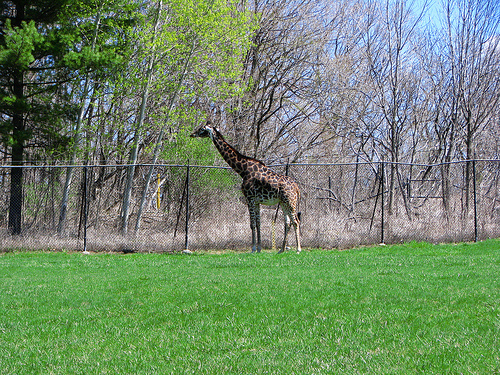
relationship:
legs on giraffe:
[283, 204, 300, 253] [188, 118, 303, 254]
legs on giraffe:
[281, 214, 291, 252] [188, 118, 303, 254]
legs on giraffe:
[254, 199, 262, 252] [188, 118, 303, 254]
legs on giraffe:
[247, 203, 256, 253] [188, 118, 303, 254]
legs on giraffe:
[242, 193, 308, 255] [188, 118, 303, 254]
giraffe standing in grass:
[188, 118, 303, 254] [2, 251, 499, 371]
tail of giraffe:
[295, 186, 302, 221] [188, 118, 303, 254]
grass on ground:
[2, 251, 499, 371] [1, 223, 497, 372]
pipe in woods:
[146, 171, 172, 218] [5, 2, 495, 254]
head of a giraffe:
[192, 119, 224, 144] [178, 105, 301, 243]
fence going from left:
[6, 156, 481, 250] [7, 10, 65, 280]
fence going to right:
[6, 156, 481, 250] [413, 23, 487, 307]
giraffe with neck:
[188, 118, 303, 254] [214, 136, 251, 176]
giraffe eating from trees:
[188, 118, 303, 254] [8, 7, 498, 158]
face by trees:
[187, 123, 204, 137] [69, 29, 370, 116]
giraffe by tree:
[188, 118, 303, 254] [24, 25, 489, 137]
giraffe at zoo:
[188, 118, 303, 254] [1, 4, 497, 372]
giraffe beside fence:
[188, 118, 303, 254] [6, 156, 481, 250]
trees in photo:
[363, 80, 425, 158] [7, 5, 495, 373]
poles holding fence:
[170, 158, 196, 249] [6, 156, 481, 250]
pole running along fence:
[0, 158, 497, 168] [6, 156, 481, 250]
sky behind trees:
[323, 2, 498, 81] [3, 2, 499, 226]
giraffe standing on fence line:
[188, 118, 303, 254] [2, 236, 491, 256]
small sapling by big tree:
[56, 0, 191, 244] [2, 0, 34, 251]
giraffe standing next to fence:
[188, 118, 303, 254] [1, 162, 498, 251]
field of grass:
[0, 235, 498, 373] [1, 236, 498, 373]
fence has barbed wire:
[6, 156, 481, 250] [1, 151, 499, 161]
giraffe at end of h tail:
[183, 112, 312, 260] [291, 177, 307, 228]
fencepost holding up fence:
[78, 157, 88, 256] [6, 156, 481, 250]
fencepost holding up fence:
[374, 154, 387, 243] [6, 156, 481, 250]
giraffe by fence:
[188, 118, 303, 254] [6, 156, 481, 250]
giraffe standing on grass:
[183, 112, 312, 260] [2, 251, 499, 371]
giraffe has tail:
[183, 112, 312, 260] [293, 182, 303, 222]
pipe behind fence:
[156, 173, 161, 210] [337, 158, 489, 238]